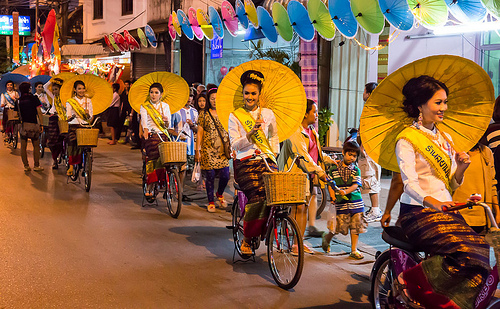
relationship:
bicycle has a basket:
[224, 151, 311, 295] [257, 172, 307, 207]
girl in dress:
[392, 74, 499, 309] [393, 202, 496, 308]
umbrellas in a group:
[103, 3, 497, 54] [169, 10, 329, 43]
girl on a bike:
[392, 74, 499, 309] [367, 200, 497, 306]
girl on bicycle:
[228, 71, 284, 258] [224, 151, 311, 291]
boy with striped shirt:
[323, 142, 367, 258] [325, 157, 365, 215]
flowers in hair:
[242, 71, 264, 87] [239, 70, 263, 88]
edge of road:
[99, 130, 137, 149] [3, 114, 394, 307]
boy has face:
[323, 142, 367, 258] [342, 151, 359, 164]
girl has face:
[392, 74, 499, 309] [428, 90, 448, 123]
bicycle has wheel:
[224, 151, 311, 291] [266, 216, 303, 290]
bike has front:
[139, 123, 184, 226] [154, 128, 185, 217]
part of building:
[76, 1, 175, 39] [83, 2, 174, 83]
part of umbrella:
[281, 86, 308, 121] [216, 59, 307, 144]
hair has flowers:
[239, 70, 263, 88] [242, 71, 264, 87]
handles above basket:
[242, 154, 313, 172] [257, 172, 307, 207]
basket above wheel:
[257, 172, 307, 207] [266, 216, 303, 290]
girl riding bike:
[392, 74, 499, 309] [367, 200, 497, 306]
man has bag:
[15, 83, 44, 175] [22, 119, 40, 139]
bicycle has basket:
[224, 151, 311, 291] [257, 172, 307, 207]